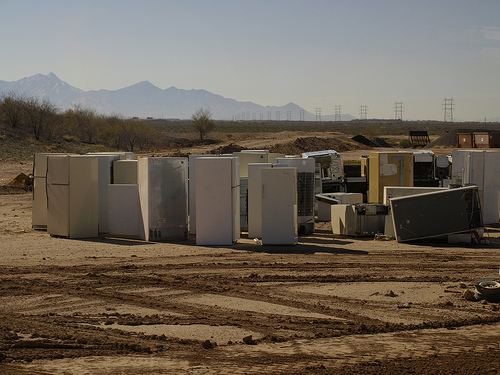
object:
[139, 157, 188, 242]
fridges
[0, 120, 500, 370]
junk yard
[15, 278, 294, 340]
tire tracks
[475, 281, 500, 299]
wheel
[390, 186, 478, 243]
back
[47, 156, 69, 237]
front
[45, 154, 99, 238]
fridge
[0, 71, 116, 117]
mountains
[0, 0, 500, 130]
background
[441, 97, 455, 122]
power poles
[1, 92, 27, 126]
trees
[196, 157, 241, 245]
fridge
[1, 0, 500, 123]
sky